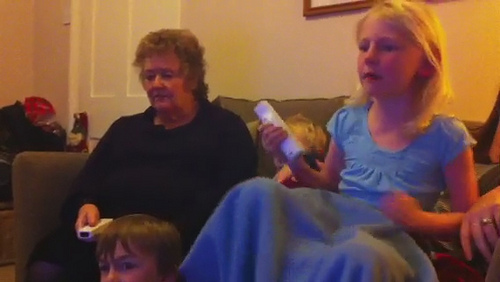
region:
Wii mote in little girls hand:
[240, 89, 304, 169]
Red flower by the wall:
[11, 70, 57, 126]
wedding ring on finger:
[476, 210, 492, 232]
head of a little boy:
[98, 220, 175, 277]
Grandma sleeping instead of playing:
[120, 30, 212, 110]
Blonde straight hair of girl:
[401, 3, 468, 120]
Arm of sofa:
[16, 147, 60, 188]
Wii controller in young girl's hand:
[251, 97, 305, 162]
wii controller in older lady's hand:
[73, 214, 110, 239]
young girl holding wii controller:
[184, 0, 481, 280]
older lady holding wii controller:
[37, 26, 257, 280]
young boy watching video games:
[90, 210, 182, 280]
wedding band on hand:
[481, 213, 493, 225]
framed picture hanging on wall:
[298, 0, 457, 18]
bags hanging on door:
[63, 108, 93, 152]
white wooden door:
[64, 0, 182, 153]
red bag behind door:
[20, 93, 56, 122]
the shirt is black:
[83, 103, 257, 219]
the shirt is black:
[94, 105, 228, 217]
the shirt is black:
[77, 102, 244, 224]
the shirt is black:
[79, 108, 237, 253]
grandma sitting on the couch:
[89, 44, 251, 247]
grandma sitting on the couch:
[82, 24, 294, 276]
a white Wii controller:
[254, 100, 304, 165]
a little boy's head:
[92, 216, 187, 279]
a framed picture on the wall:
[298, 0, 401, 17]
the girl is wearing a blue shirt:
[328, 101, 477, 221]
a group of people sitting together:
[77, 7, 494, 280]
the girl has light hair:
[351, 0, 451, 132]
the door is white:
[69, 0, 183, 140]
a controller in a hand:
[253, 97, 310, 164]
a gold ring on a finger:
[478, 212, 493, 228]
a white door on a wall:
[73, 2, 144, 139]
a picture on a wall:
[294, 4, 381, 16]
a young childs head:
[96, 216, 180, 276]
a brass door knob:
[71, 109, 86, 120]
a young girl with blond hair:
[189, 2, 484, 272]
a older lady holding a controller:
[53, 26, 250, 244]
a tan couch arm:
[11, 142, 81, 247]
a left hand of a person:
[452, 195, 499, 261]